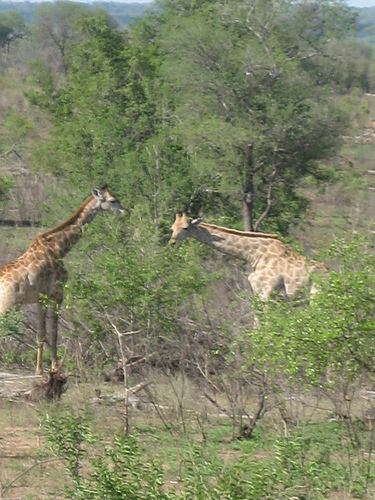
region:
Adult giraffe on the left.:
[0, 183, 132, 375]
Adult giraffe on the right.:
[168, 206, 336, 384]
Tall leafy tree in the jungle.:
[31, 12, 196, 183]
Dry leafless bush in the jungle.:
[109, 316, 283, 439]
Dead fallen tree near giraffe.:
[2, 348, 78, 403]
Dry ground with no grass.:
[7, 425, 47, 477]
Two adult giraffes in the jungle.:
[0, 181, 343, 393]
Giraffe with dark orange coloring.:
[0, 178, 132, 376]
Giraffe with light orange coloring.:
[166, 208, 344, 388]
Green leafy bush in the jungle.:
[32, 403, 372, 498]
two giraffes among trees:
[2, 174, 329, 380]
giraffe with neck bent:
[167, 208, 326, 317]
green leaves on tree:
[300, 294, 357, 364]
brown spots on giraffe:
[22, 255, 42, 282]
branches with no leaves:
[110, 328, 163, 408]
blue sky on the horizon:
[353, 0, 369, 21]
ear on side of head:
[86, 184, 107, 210]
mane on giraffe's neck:
[218, 224, 263, 238]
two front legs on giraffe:
[30, 304, 63, 379]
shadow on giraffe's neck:
[186, 226, 229, 249]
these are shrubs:
[57, 279, 371, 489]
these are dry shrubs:
[109, 342, 251, 447]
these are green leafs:
[223, 296, 366, 384]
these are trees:
[72, 23, 363, 209]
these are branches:
[174, 0, 320, 210]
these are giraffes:
[51, 168, 336, 372]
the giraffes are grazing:
[32, 182, 248, 257]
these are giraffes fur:
[19, 214, 90, 245]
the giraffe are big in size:
[163, 207, 344, 389]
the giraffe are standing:
[0, 21, 164, 386]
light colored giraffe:
[165, 210, 342, 368]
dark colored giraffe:
[0, 180, 131, 383]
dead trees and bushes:
[87, 294, 318, 434]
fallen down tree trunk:
[0, 360, 82, 407]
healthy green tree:
[33, 12, 179, 301]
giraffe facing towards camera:
[165, 210, 196, 252]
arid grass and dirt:
[2, 406, 371, 493]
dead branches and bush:
[93, 383, 254, 418]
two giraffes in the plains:
[0, 180, 334, 396]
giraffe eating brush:
[163, 207, 338, 330]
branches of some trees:
[217, 88, 271, 142]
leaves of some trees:
[106, 452, 140, 484]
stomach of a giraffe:
[13, 264, 34, 296]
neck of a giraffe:
[219, 231, 244, 256]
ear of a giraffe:
[190, 212, 202, 230]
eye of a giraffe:
[107, 191, 119, 204]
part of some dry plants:
[141, 334, 193, 409]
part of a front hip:
[239, 260, 283, 288]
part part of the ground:
[147, 430, 178, 460]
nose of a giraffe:
[166, 234, 174, 251]